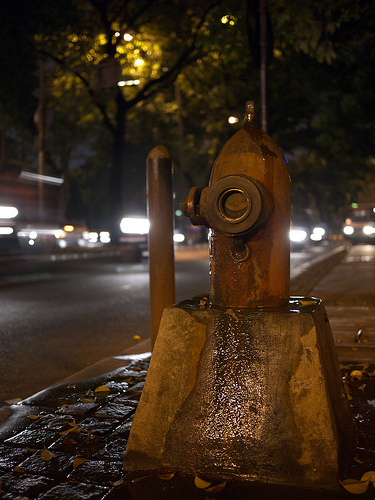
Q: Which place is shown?
A: It is a sidewalk.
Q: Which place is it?
A: It is a sidewalk.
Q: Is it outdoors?
A: Yes, it is outdoors.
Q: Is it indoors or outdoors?
A: It is outdoors.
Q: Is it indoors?
A: No, it is outdoors.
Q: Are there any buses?
A: No, there are no buses.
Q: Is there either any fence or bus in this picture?
A: No, there are no buses or fences.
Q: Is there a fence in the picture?
A: No, there are no fences.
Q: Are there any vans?
A: No, there are no vans.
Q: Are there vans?
A: No, there are no vans.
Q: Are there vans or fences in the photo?
A: No, there are no vans or fences.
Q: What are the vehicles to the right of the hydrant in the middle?
A: The vehicles are cars.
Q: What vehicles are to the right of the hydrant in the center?
A: The vehicles are cars.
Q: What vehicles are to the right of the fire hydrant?
A: The vehicles are cars.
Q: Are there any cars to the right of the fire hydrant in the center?
A: Yes, there are cars to the right of the hydrant.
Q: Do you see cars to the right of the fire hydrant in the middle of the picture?
A: Yes, there are cars to the right of the hydrant.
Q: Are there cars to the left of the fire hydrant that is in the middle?
A: No, the cars are to the right of the fire hydrant.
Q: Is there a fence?
A: No, there are no fences.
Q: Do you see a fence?
A: No, there are no fences.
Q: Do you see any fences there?
A: No, there are no fences.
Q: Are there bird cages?
A: No, there are no bird cages.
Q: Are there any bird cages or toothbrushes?
A: No, there are no bird cages or toothbrushes.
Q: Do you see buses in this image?
A: No, there are no buses.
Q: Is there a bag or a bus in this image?
A: No, there are no buses or bags.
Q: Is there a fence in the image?
A: No, there are no fences.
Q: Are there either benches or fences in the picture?
A: No, there are no fences or benches.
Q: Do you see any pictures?
A: No, there are no pictures.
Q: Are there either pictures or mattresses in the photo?
A: No, there are no pictures or mattresses.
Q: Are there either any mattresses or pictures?
A: No, there are no pictures or mattresses.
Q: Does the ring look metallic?
A: Yes, the ring is metallic.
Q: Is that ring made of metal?
A: Yes, the ring is made of metal.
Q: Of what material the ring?
A: The ring is made of metal.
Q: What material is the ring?
A: The ring is made of metal.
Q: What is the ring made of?
A: The ring is made of metal.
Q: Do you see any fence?
A: No, there are no fences.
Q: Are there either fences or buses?
A: No, there are no fences or buses.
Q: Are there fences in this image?
A: No, there are no fences.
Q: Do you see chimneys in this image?
A: No, there are no chimneys.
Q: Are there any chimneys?
A: No, there are no chimneys.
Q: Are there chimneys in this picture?
A: No, there are no chimneys.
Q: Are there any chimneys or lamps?
A: No, there are no chimneys or lamps.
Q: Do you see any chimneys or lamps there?
A: No, there are no chimneys or lamps.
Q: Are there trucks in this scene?
A: No, there are no trucks.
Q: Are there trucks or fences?
A: No, there are no trucks or fences.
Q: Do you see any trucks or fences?
A: No, there are no trucks or fences.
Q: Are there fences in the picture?
A: No, there are no fences.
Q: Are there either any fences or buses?
A: No, there are no fences or buses.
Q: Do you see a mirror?
A: No, there are no mirrors.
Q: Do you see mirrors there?
A: No, there are no mirrors.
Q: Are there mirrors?
A: No, there are no mirrors.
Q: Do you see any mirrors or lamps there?
A: No, there are no mirrors or lamps.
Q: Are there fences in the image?
A: No, there are no fences.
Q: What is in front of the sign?
A: The tree is in front of the sign.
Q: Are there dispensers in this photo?
A: No, there are no dispensers.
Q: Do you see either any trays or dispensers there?
A: No, there are no dispensers or trays.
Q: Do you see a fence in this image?
A: No, there are no fences.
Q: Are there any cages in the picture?
A: No, there are no cages.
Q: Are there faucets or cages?
A: No, there are no cages or faucets.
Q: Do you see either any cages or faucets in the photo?
A: No, there are no cages or faucets.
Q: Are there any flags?
A: No, there are no flags.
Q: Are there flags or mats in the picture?
A: No, there are no flags or mats.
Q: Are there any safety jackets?
A: No, there are no safety jackets.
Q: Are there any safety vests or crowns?
A: No, there are no safety vests or crowns.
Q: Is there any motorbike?
A: No, there are no motorcycles.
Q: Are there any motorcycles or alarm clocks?
A: No, there are no motorcycles or alarm clocks.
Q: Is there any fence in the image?
A: No, there are no fences.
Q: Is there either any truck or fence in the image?
A: No, there are no fences or trucks.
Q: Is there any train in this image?
A: No, there are no trains.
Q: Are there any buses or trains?
A: No, there are no trains or buses.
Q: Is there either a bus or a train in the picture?
A: No, there are no trains or buses.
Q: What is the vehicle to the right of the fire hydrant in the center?
A: The vehicle is a car.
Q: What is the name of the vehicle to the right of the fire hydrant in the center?
A: The vehicle is a car.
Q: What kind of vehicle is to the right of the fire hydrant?
A: The vehicle is a car.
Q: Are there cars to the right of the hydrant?
A: Yes, there is a car to the right of the hydrant.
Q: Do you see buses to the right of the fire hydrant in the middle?
A: No, there is a car to the right of the fire hydrant.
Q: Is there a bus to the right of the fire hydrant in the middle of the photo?
A: No, there is a car to the right of the fire hydrant.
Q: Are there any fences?
A: No, there are no fences.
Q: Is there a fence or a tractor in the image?
A: No, there are no fences or tractors.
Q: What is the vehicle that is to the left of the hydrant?
A: The vehicle is a car.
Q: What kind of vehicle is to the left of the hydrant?
A: The vehicle is a car.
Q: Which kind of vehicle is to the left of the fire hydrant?
A: The vehicle is a car.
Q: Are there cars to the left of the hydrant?
A: Yes, there is a car to the left of the hydrant.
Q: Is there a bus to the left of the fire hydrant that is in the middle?
A: No, there is a car to the left of the fire hydrant.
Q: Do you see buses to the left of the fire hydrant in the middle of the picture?
A: No, there is a car to the left of the fire hydrant.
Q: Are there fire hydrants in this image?
A: Yes, there is a fire hydrant.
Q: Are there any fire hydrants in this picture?
A: Yes, there is a fire hydrant.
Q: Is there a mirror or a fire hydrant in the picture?
A: Yes, there is a fire hydrant.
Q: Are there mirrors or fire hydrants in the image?
A: Yes, there is a fire hydrant.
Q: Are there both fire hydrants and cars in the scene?
A: Yes, there are both a fire hydrant and a car.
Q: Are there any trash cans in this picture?
A: No, there are no trash cans.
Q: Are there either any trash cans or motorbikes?
A: No, there are no trash cans or motorbikes.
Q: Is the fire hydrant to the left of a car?
A: Yes, the fire hydrant is to the left of a car.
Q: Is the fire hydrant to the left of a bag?
A: No, the fire hydrant is to the left of a car.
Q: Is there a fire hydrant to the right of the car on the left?
A: Yes, there is a fire hydrant to the right of the car.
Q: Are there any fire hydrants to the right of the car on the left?
A: Yes, there is a fire hydrant to the right of the car.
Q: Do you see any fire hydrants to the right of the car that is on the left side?
A: Yes, there is a fire hydrant to the right of the car.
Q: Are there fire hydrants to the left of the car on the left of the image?
A: No, the fire hydrant is to the right of the car.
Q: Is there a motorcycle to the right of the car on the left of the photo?
A: No, there is a fire hydrant to the right of the car.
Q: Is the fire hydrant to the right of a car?
A: Yes, the fire hydrant is to the right of a car.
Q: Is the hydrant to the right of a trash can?
A: No, the hydrant is to the right of a car.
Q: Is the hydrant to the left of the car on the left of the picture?
A: No, the hydrant is to the right of the car.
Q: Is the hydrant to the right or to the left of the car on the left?
A: The hydrant is to the right of the car.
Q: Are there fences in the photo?
A: No, there are no fences.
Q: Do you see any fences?
A: No, there are no fences.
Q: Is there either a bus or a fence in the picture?
A: No, there are no fences or buses.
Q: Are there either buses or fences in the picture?
A: No, there are no fences or buses.